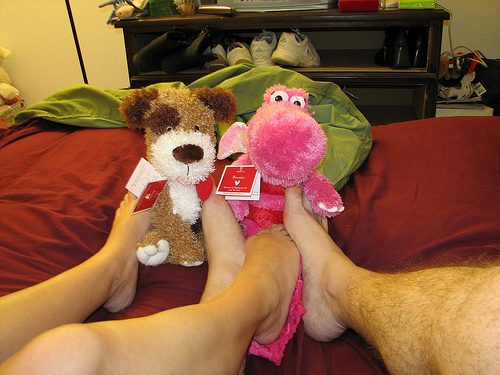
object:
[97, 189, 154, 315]
foot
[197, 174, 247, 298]
foot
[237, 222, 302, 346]
foot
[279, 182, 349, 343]
foot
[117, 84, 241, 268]
dog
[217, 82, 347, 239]
stuffed animal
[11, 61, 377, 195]
blanket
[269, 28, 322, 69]
shoes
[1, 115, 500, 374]
comfortor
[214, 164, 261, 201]
tag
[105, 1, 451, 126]
shelf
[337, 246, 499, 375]
hair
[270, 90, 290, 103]
eyes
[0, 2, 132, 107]
wall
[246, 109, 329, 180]
nose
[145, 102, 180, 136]
spot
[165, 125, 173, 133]
eyes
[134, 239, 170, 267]
dog's foot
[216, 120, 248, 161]
wing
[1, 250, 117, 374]
leg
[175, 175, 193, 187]
tongue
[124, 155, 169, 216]
tag